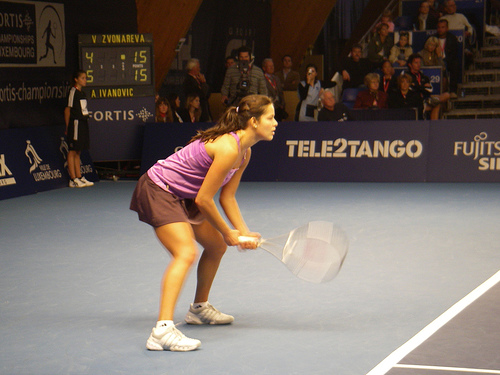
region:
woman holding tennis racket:
[133, 95, 347, 353]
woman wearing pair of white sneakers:
[146, 325, 196, 351]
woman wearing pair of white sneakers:
[186, 307, 232, 323]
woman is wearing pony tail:
[130, 90, 278, 353]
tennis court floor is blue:
[2, 176, 498, 373]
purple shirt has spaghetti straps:
[147, 129, 241, 197]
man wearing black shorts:
[60, 63, 93, 186]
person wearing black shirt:
[389, 76, 424, 117]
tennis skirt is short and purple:
[128, 167, 213, 226]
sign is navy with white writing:
[121, 121, 497, 180]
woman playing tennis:
[128, 93, 354, 355]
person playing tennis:
[123, 107, 342, 352]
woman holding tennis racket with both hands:
[139, 73, 370, 364]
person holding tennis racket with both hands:
[148, 74, 337, 354]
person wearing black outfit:
[61, 63, 101, 192]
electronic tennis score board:
[79, 27, 154, 87]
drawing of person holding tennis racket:
[31, 5, 69, 69]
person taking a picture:
[284, 60, 319, 105]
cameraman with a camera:
[226, 42, 263, 92]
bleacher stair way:
[456, 47, 499, 116]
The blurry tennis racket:
[218, 225, 355, 285]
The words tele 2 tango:
[288, 136, 422, 160]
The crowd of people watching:
[174, 19, 492, 111]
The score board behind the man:
[81, 33, 153, 95]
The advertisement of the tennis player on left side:
[40, 2, 67, 67]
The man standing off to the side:
[67, 73, 94, 187]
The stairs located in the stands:
[452, 29, 497, 114]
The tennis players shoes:
[148, 303, 236, 348]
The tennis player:
[137, 93, 354, 351]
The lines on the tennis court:
[388, 272, 479, 372]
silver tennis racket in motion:
[256, 214, 372, 300]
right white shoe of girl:
[146, 315, 196, 361]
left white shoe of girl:
[186, 295, 235, 338]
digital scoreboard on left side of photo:
[75, 34, 158, 152]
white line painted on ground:
[421, 270, 464, 344]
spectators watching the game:
[348, 41, 428, 116]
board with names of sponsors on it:
[291, 127, 494, 183]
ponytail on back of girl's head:
[211, 89, 237, 137]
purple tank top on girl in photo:
[171, 139, 223, 189]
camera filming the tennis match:
[226, 48, 260, 92]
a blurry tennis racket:
[236, 225, 348, 275]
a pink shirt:
[150, 133, 245, 191]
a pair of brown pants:
[125, 177, 203, 224]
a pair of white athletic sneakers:
[145, 302, 232, 354]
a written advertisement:
[280, 137, 423, 157]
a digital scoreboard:
[83, 32, 151, 157]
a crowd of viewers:
[148, 1, 496, 115]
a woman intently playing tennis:
[128, 94, 347, 350]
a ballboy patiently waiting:
[60, 66, 102, 188]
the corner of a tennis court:
[371, 272, 498, 372]